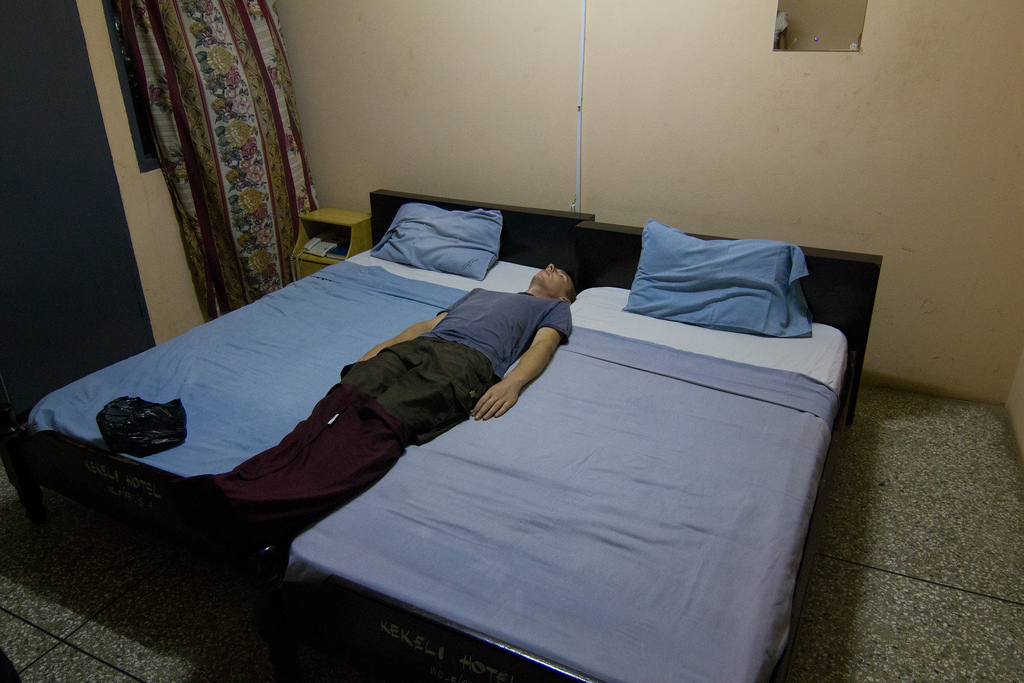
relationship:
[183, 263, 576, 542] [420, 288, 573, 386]
man wearing shirt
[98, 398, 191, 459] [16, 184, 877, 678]
bag on bed bed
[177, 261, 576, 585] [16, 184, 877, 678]
man on bed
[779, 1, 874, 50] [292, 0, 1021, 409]
marrow on wall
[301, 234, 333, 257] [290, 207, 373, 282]
phone on night stand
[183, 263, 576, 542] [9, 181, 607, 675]
man between bed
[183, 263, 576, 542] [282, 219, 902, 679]
man between bed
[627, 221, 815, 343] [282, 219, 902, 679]
pillow on bed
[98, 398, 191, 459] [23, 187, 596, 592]
bag on bed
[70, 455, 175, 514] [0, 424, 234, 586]
writing on headboard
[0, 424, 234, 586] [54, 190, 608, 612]
headboard on bed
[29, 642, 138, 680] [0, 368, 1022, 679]
tile on floor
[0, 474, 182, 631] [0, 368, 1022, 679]
tile on floor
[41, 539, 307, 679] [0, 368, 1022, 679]
tile on floor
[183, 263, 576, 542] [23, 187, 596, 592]
man laying between bed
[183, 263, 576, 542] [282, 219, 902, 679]
man laying between bed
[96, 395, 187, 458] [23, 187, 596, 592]
bag on bed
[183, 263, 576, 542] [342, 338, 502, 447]
man wearing khaki's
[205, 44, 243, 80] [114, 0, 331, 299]
flower on curtain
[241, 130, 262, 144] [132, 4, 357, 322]
flower on curtain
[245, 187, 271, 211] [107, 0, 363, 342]
flower on curtain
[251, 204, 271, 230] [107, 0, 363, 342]
flower on curtain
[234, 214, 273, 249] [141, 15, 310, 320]
flower on curtain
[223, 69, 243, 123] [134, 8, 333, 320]
flower on curtain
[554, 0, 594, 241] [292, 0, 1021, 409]
white cord against wall